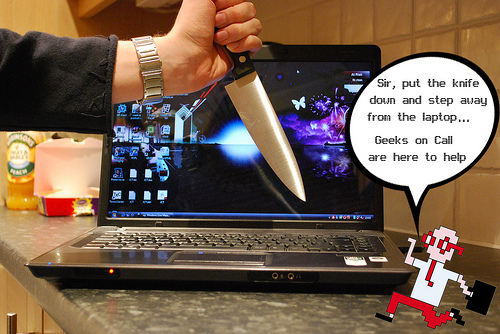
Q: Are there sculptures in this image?
A: No, there are no sculptures.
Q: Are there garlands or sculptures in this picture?
A: No, there are no sculptures or garlands.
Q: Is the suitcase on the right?
A: Yes, the suitcase is on the right of the image.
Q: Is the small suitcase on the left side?
A: No, the suitcase is on the right of the image.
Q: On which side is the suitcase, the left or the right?
A: The suitcase is on the right of the image.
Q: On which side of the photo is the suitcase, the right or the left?
A: The suitcase is on the right of the image.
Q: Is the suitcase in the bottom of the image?
A: Yes, the suitcase is in the bottom of the image.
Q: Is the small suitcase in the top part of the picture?
A: No, the suitcase is in the bottom of the image.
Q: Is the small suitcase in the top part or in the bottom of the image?
A: The suitcase is in the bottom of the image.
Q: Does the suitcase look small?
A: Yes, the suitcase is small.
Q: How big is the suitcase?
A: The suitcase is small.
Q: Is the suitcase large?
A: No, the suitcase is small.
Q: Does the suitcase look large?
A: No, the suitcase is small.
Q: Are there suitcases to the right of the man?
A: Yes, there is a suitcase to the right of the man.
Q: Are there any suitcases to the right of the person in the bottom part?
A: Yes, there is a suitcase to the right of the man.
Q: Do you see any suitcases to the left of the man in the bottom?
A: No, the suitcase is to the right of the man.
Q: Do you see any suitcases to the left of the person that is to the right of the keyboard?
A: No, the suitcase is to the right of the man.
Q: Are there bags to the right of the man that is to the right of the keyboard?
A: No, there is a suitcase to the right of the man.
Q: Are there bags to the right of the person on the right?
A: No, there is a suitcase to the right of the man.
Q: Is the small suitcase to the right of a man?
A: Yes, the suitcase is to the right of a man.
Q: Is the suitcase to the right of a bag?
A: No, the suitcase is to the right of a man.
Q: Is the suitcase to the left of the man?
A: No, the suitcase is to the right of the man.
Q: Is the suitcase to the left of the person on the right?
A: No, the suitcase is to the right of the man.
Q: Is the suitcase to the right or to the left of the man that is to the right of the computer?
A: The suitcase is to the right of the man.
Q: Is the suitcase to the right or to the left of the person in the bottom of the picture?
A: The suitcase is to the right of the man.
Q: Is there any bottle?
A: Yes, there is a bottle.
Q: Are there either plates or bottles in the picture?
A: Yes, there is a bottle.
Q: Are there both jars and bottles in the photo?
A: No, there is a bottle but no jars.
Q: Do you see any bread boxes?
A: No, there are no bread boxes.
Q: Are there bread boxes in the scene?
A: No, there are no bread boxes.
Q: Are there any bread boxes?
A: No, there are no bread boxes.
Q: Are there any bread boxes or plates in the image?
A: No, there are no bread boxes or plates.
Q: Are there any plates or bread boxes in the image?
A: No, there are no bread boxes or plates.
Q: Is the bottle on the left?
A: Yes, the bottle is on the left of the image.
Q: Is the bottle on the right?
A: No, the bottle is on the left of the image.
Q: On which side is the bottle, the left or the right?
A: The bottle is on the left of the image.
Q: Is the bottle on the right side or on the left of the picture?
A: The bottle is on the left of the image.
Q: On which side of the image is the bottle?
A: The bottle is on the left of the image.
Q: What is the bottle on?
A: The bottle is on the counter.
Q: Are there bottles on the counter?
A: Yes, there is a bottle on the counter.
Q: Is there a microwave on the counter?
A: No, there is a bottle on the counter.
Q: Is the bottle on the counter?
A: Yes, the bottle is on the counter.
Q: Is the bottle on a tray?
A: No, the bottle is on the counter.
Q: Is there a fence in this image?
A: No, there are no fences.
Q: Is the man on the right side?
A: Yes, the man is on the right of the image.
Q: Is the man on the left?
A: No, the man is on the right of the image.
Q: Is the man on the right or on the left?
A: The man is on the right of the image.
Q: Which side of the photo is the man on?
A: The man is on the right of the image.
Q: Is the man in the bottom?
A: Yes, the man is in the bottom of the image.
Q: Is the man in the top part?
A: No, the man is in the bottom of the image.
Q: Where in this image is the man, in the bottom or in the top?
A: The man is in the bottom of the image.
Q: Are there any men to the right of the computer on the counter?
A: Yes, there is a man to the right of the computer.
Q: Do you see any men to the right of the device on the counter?
A: Yes, there is a man to the right of the computer.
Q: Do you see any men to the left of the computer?
A: No, the man is to the right of the computer.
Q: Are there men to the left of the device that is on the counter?
A: No, the man is to the right of the computer.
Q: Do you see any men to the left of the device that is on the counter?
A: No, the man is to the right of the computer.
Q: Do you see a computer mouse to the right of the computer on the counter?
A: No, there is a man to the right of the computer.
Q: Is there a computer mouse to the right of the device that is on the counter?
A: No, there is a man to the right of the computer.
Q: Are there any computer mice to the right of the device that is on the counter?
A: No, there is a man to the right of the computer.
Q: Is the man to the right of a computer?
A: Yes, the man is to the right of a computer.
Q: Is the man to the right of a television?
A: No, the man is to the right of a computer.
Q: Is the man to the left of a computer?
A: No, the man is to the right of a computer.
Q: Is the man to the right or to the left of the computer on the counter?
A: The man is to the right of the computer.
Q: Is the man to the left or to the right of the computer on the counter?
A: The man is to the right of the computer.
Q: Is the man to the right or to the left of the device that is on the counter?
A: The man is to the right of the computer.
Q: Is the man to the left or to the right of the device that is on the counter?
A: The man is to the right of the computer.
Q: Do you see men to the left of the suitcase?
A: Yes, there is a man to the left of the suitcase.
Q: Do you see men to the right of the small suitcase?
A: No, the man is to the left of the suitcase.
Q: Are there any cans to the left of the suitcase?
A: No, there is a man to the left of the suitcase.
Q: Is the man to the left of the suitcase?
A: Yes, the man is to the left of the suitcase.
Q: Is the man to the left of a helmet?
A: No, the man is to the left of the suitcase.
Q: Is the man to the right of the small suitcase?
A: No, the man is to the left of the suitcase.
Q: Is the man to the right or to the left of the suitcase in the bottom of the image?
A: The man is to the left of the suitcase.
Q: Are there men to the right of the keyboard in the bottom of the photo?
A: Yes, there is a man to the right of the keyboard.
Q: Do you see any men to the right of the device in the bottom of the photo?
A: Yes, there is a man to the right of the keyboard.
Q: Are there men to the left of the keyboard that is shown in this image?
A: No, the man is to the right of the keyboard.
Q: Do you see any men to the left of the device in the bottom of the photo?
A: No, the man is to the right of the keyboard.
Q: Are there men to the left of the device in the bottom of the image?
A: No, the man is to the right of the keyboard.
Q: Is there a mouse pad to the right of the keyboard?
A: No, there is a man to the right of the keyboard.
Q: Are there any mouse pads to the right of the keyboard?
A: No, there is a man to the right of the keyboard.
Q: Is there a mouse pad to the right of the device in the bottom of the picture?
A: No, there is a man to the right of the keyboard.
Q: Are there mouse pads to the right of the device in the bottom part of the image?
A: No, there is a man to the right of the keyboard.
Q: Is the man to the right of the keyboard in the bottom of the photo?
A: Yes, the man is to the right of the keyboard.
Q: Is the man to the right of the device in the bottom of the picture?
A: Yes, the man is to the right of the keyboard.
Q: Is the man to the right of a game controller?
A: No, the man is to the right of the keyboard.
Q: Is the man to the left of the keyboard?
A: No, the man is to the right of the keyboard.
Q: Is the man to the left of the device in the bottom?
A: No, the man is to the right of the keyboard.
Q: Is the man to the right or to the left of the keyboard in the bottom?
A: The man is to the right of the keyboard.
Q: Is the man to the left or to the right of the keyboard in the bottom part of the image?
A: The man is to the right of the keyboard.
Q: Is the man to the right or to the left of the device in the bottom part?
A: The man is to the right of the keyboard.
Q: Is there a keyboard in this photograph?
A: Yes, there is a keyboard.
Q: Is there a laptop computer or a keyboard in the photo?
A: Yes, there is a keyboard.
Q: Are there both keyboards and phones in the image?
A: No, there is a keyboard but no phones.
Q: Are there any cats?
A: No, there are no cats.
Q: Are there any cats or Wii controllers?
A: No, there are no cats or Wii controllers.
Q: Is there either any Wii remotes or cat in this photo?
A: No, there are no cats or Wii controllers.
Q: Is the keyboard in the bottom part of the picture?
A: Yes, the keyboard is in the bottom of the image.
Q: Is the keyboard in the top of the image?
A: No, the keyboard is in the bottom of the image.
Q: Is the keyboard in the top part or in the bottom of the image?
A: The keyboard is in the bottom of the image.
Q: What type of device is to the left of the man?
A: The device is a keyboard.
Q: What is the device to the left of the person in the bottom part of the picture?
A: The device is a keyboard.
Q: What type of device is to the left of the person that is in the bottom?
A: The device is a keyboard.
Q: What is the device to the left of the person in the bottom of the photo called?
A: The device is a keyboard.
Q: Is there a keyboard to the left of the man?
A: Yes, there is a keyboard to the left of the man.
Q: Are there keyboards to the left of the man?
A: Yes, there is a keyboard to the left of the man.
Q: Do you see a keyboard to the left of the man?
A: Yes, there is a keyboard to the left of the man.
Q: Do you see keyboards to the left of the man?
A: Yes, there is a keyboard to the left of the man.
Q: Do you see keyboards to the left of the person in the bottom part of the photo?
A: Yes, there is a keyboard to the left of the man.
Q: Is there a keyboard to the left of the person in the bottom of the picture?
A: Yes, there is a keyboard to the left of the man.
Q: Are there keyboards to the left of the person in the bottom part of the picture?
A: Yes, there is a keyboard to the left of the man.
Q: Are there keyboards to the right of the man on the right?
A: No, the keyboard is to the left of the man.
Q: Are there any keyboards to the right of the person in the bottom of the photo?
A: No, the keyboard is to the left of the man.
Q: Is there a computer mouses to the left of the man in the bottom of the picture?
A: No, there is a keyboard to the left of the man.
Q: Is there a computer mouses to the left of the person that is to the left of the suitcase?
A: No, there is a keyboard to the left of the man.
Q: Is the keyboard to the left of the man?
A: Yes, the keyboard is to the left of the man.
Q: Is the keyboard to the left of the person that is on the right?
A: Yes, the keyboard is to the left of the man.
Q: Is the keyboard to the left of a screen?
A: No, the keyboard is to the left of the man.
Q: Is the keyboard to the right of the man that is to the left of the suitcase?
A: No, the keyboard is to the left of the man.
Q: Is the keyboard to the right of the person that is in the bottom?
A: No, the keyboard is to the left of the man.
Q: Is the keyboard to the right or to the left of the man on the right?
A: The keyboard is to the left of the man.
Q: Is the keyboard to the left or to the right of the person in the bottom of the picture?
A: The keyboard is to the left of the man.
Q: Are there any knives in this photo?
A: Yes, there is a knife.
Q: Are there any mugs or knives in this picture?
A: Yes, there is a knife.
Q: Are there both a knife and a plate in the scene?
A: No, there is a knife but no plates.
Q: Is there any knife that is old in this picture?
A: Yes, there is an old knife.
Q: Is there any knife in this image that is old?
A: Yes, there is a knife that is old.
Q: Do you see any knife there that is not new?
A: Yes, there is a old knife.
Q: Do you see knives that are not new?
A: Yes, there is a old knife.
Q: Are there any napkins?
A: No, there are no napkins.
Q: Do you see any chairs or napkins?
A: No, there are no napkins or chairs.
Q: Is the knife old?
A: Yes, the knife is old.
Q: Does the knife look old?
A: Yes, the knife is old.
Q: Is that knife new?
A: No, the knife is old.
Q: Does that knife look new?
A: No, the knife is old.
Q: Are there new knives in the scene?
A: No, there is a knife but it is old.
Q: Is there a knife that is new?
A: No, there is a knife but it is old.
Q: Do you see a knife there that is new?
A: No, there is a knife but it is old.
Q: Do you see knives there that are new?
A: No, there is a knife but it is old.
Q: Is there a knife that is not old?
A: No, there is a knife but it is old.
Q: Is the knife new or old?
A: The knife is old.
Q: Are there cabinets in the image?
A: Yes, there is a cabinet.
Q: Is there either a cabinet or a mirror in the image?
A: Yes, there is a cabinet.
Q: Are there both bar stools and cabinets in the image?
A: No, there is a cabinet but no bar stools.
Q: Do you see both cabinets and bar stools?
A: No, there is a cabinet but no bar stools.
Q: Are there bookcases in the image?
A: No, there are no bookcases.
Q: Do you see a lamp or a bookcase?
A: No, there are no bookcases or lamps.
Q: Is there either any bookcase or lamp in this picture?
A: No, there are no bookcases or lamps.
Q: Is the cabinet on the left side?
A: Yes, the cabinet is on the left of the image.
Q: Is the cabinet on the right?
A: No, the cabinet is on the left of the image.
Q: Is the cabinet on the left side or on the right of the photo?
A: The cabinet is on the left of the image.